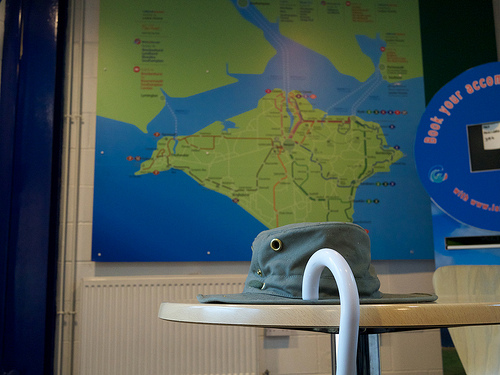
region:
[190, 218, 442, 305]
a blue hat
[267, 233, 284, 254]
a hole on hat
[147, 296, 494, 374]
a round table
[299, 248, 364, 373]
a handle on table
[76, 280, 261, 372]
the lines on wall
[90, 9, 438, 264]
a map of the world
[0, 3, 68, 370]
a blue door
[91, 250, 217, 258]
the tats on wall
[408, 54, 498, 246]
a circle of advertising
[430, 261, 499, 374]
an oak wood bench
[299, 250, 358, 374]
A white hook coming off a table.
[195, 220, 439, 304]
A grey hat sitting on a small table.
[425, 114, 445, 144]
The orange word Book on a blue oval.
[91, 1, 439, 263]
A blue and green map with orange markers.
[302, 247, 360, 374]
A white cane coming off the side of a brown table.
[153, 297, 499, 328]
A light brown table top.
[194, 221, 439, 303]
A large grey hat on the table top.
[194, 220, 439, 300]
A grey hat sitting on a table top.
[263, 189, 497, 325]
This is a hat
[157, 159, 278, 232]
This is a map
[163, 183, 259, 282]
The map is blue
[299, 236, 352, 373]
This is a cane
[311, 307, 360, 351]
The cane is plastic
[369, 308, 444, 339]
This is a table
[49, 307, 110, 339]
This is a metal pole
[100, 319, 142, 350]
This is a vent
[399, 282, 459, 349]
The table is wooden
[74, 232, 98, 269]
The wall is concrete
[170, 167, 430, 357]
hat on the table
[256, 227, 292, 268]
hole on side of hat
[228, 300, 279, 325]
side of the table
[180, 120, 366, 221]
map in the background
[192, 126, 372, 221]
land on the map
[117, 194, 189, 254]
water on the map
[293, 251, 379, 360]
white object in photo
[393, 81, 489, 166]
red writing on a surface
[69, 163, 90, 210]
white wall behind map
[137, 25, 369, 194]
green pieces of land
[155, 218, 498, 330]
a hat is on a table in the room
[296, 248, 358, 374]
a white cane is hooked onto the table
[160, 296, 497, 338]
the roundtable top is beige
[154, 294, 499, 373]
the table has a chrome pedestal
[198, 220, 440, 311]
the gray hat has air vents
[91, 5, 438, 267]
a map is on the wall behind the table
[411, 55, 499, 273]
a blue sign is next to the table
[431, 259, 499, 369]
a wooden chair is near the table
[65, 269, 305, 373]
a wall heater is below the map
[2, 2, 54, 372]
a blue pipe is to the side of the map